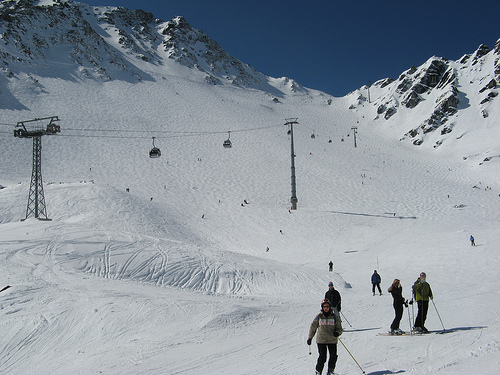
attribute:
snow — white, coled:
[0, 1, 499, 374]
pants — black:
[317, 344, 338, 373]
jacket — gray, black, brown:
[307, 311, 343, 344]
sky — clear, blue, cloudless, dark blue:
[86, 0, 499, 98]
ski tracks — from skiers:
[75, 237, 249, 293]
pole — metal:
[284, 115, 298, 210]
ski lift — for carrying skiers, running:
[0, 82, 372, 219]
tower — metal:
[14, 115, 61, 222]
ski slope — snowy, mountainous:
[0, 78, 498, 374]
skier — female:
[386, 278, 409, 335]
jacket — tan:
[412, 279, 434, 303]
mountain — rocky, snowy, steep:
[0, 1, 334, 100]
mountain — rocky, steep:
[345, 35, 500, 160]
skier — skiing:
[323, 281, 342, 320]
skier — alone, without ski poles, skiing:
[370, 269, 383, 293]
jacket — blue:
[371, 272, 381, 286]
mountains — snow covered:
[0, 1, 499, 169]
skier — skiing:
[468, 234, 475, 247]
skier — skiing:
[265, 246, 270, 252]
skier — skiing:
[242, 198, 248, 205]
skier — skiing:
[202, 213, 206, 219]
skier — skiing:
[217, 199, 222, 205]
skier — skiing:
[150, 196, 154, 201]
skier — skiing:
[361, 179, 364, 184]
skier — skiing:
[163, 183, 167, 190]